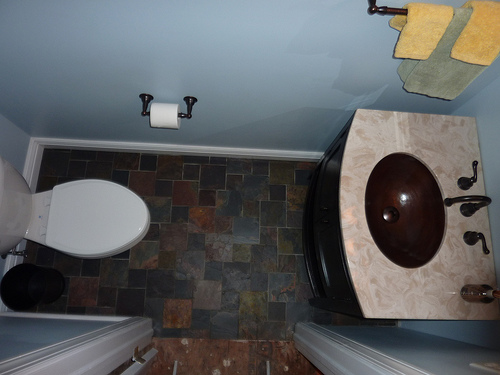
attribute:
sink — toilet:
[0, 164, 155, 259]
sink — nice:
[360, 139, 453, 276]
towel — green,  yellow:
[387, 0, 456, 63]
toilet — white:
[2, 151, 171, 273]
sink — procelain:
[344, 107, 498, 325]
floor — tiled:
[168, 180, 288, 309]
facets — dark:
[445, 159, 494, 255]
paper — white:
[133, 102, 193, 132]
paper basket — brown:
[2, 264, 66, 307]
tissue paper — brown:
[146, 100, 183, 131]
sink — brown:
[361, 149, 450, 269]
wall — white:
[1, 0, 492, 157]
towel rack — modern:
[373, 7, 498, 99]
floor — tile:
[7, 148, 399, 341]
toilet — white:
[1, 154, 154, 272]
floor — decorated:
[13, 143, 365, 337]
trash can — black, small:
[0, 264, 65, 311]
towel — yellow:
[400, 2, 450, 75]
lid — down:
[32, 173, 154, 262]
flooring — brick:
[161, 162, 294, 339]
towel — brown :
[387, 2, 453, 60]